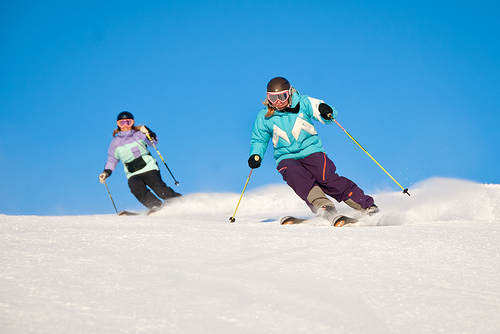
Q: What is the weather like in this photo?
A: It is clear.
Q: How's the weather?
A: It is clear.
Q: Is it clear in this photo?
A: Yes, it is clear.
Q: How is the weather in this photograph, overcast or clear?
A: It is clear.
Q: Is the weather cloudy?
A: No, it is clear.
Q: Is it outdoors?
A: Yes, it is outdoors.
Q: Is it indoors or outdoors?
A: It is outdoors.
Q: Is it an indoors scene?
A: No, it is outdoors.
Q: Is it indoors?
A: No, it is outdoors.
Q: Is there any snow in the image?
A: Yes, there is snow.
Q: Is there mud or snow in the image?
A: Yes, there is snow.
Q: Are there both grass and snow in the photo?
A: No, there is snow but no grass.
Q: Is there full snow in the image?
A: Yes, there is full snow.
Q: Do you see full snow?
A: Yes, there is full snow.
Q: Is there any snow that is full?
A: Yes, there is snow that is full.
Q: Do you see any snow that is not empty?
A: Yes, there is full snow.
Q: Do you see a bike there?
A: No, there are no bikes.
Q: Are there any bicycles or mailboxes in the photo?
A: No, there are no bicycles or mailboxes.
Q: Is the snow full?
A: Yes, the snow is full.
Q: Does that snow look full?
A: Yes, the snow is full.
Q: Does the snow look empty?
A: No, the snow is full.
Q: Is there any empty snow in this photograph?
A: No, there is snow but it is full.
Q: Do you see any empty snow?
A: No, there is snow but it is full.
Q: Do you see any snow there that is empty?
A: No, there is snow but it is full.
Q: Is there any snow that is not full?
A: No, there is snow but it is full.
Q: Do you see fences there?
A: No, there are no fences.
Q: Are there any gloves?
A: Yes, there are gloves.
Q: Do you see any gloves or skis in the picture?
A: Yes, there are gloves.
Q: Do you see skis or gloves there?
A: Yes, there are gloves.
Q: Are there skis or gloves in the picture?
A: Yes, there are gloves.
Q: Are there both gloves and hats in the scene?
A: No, there are gloves but no hats.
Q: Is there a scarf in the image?
A: No, there are no scarves.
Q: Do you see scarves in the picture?
A: No, there are no scarves.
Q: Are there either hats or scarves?
A: No, there are no scarves or hats.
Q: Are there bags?
A: No, there are no bags.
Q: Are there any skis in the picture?
A: Yes, there are skis.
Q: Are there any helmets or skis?
A: Yes, there are skis.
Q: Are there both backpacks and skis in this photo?
A: No, there are skis but no backpacks.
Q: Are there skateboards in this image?
A: No, there are no skateboards.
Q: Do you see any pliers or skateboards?
A: No, there are no skateboards or pliers.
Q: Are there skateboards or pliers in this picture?
A: No, there are no skateboards or pliers.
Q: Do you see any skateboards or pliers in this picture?
A: No, there are no skateboards or pliers.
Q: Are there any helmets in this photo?
A: Yes, there is a helmet.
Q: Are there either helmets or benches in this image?
A: Yes, there is a helmet.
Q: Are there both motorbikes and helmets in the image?
A: No, there is a helmet but no motorcycles.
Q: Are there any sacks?
A: No, there are no sacks.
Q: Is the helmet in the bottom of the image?
A: No, the helmet is in the top of the image.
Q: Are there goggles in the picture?
A: Yes, there are goggles.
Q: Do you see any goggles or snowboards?
A: Yes, there are goggles.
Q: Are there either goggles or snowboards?
A: Yes, there are goggles.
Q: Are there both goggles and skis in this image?
A: Yes, there are both goggles and a ski.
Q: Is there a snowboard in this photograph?
A: No, there are no snowboards.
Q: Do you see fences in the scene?
A: No, there are no fences.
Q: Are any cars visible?
A: No, there are no cars.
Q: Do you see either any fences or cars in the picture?
A: No, there are no cars or fences.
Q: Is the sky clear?
A: Yes, the sky is clear.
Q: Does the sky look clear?
A: Yes, the sky is clear.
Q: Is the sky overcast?
A: No, the sky is clear.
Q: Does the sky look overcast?
A: No, the sky is clear.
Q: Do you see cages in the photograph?
A: No, there are no cages.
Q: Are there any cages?
A: No, there are no cages.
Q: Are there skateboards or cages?
A: No, there are no cages or skateboards.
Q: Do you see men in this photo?
A: No, there are no men.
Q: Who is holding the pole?
A: The skier is holding the pole.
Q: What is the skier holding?
A: The skier is holding the pole.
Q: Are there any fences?
A: No, there are no fences.